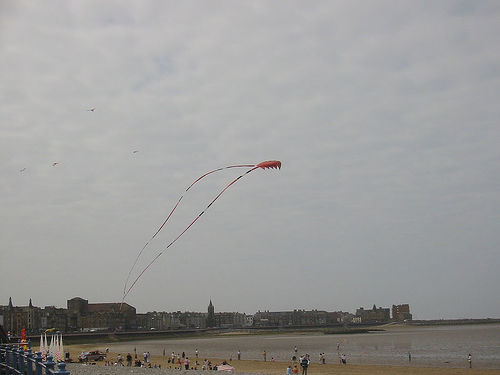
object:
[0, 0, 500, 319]
clouds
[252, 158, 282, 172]
kite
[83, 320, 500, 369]
waters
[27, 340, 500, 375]
sand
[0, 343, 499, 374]
coast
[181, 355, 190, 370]
tourists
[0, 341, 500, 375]
beach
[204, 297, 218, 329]
tower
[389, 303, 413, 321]
building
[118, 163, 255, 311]
tail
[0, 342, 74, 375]
railing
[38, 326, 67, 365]
decorations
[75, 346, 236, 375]
crowd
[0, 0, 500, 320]
sky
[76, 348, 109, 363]
automobile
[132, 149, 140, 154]
bird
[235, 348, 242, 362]
people